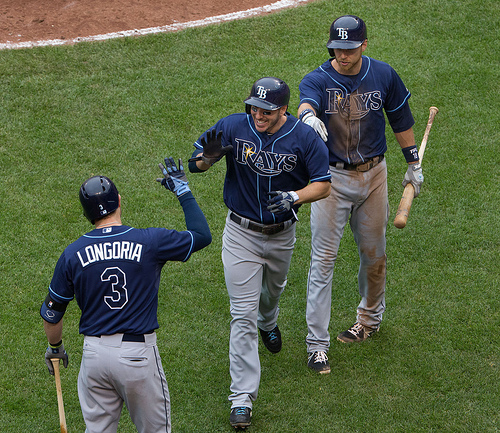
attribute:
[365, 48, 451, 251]
bat — dirty, brown, wooden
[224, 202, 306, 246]
belt — dark, brown, black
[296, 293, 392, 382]
shoes — navy, blue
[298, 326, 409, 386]
laces — white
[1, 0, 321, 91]
border — chalk, white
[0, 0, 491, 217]
field — green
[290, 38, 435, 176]
jersey — tampa bay rays, grey, dirty, blue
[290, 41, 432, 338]
uniform — white, blue, dirty, grey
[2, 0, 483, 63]
grass — green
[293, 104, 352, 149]
glove — white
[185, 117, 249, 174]
glove — black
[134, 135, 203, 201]
glove — blue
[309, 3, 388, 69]
hat — hard, blue, dark, tampa bay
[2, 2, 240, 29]
clay — red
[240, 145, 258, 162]
star — yellow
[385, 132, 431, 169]
wrist band — black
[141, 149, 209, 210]
gloves — black, grey, light blue, blue, dark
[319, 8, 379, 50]
helmet — shiny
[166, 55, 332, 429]
player — high fiving, smiling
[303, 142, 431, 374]
pants — dirty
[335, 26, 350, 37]
letters — white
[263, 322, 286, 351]
laces — blye